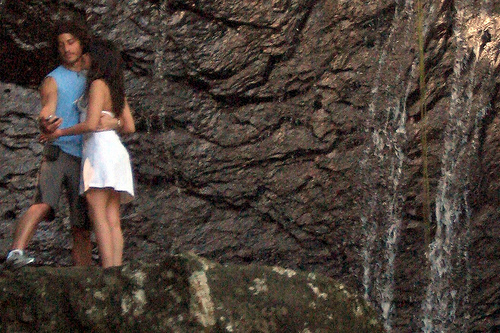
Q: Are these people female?
A: No, they are both male and female.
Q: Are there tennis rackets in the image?
A: No, there are no tennis rackets.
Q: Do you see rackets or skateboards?
A: No, there are no rackets or skateboards.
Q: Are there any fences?
A: No, there are no fences.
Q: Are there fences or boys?
A: No, there are no fences or boys.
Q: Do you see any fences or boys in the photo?
A: No, there are no fences or boys.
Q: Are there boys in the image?
A: No, there are no boys.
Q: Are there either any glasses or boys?
A: No, there are no boys or glasses.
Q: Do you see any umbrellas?
A: No, there are no umbrellas.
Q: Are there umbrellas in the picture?
A: No, there are no umbrellas.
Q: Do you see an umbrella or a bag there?
A: No, there are no umbrellas or bags.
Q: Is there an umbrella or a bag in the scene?
A: No, there are no umbrellas or bags.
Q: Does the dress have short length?
A: Yes, the dress is short.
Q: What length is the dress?
A: The dress is short.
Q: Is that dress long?
A: No, the dress is short.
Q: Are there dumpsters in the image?
A: No, there are no dumpsters.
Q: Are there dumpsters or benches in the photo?
A: No, there are no dumpsters or benches.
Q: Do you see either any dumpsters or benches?
A: No, there are no dumpsters or benches.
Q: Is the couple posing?
A: Yes, the couple is posing.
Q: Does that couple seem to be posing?
A: Yes, the couple is posing.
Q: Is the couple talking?
A: No, the couple is posing.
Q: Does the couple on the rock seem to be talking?
A: No, the couple is posing.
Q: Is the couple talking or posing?
A: The couple is posing.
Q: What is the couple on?
A: The couple is on the rock.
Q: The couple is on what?
A: The couple is on the rock.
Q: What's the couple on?
A: The couple is on the rock.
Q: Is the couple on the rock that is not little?
A: Yes, the couple is on the rock.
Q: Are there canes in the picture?
A: No, there are no canes.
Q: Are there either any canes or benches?
A: No, there are no canes or benches.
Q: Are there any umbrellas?
A: No, there are no umbrellas.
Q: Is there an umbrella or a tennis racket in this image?
A: No, there are no umbrellas or rackets.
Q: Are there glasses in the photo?
A: No, there are no glasses.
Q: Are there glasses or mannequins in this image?
A: No, there are no glasses or mannequins.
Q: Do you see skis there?
A: No, there are no skis.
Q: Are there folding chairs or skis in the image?
A: No, there are no skis or folding chairs.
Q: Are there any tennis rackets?
A: No, there are no tennis rackets.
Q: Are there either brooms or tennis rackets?
A: No, there are no tennis rackets or brooms.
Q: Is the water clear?
A: Yes, the water is clear.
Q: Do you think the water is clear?
A: Yes, the water is clear.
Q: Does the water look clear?
A: Yes, the water is clear.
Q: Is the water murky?
A: No, the water is clear.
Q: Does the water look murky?
A: No, the water is clear.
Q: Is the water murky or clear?
A: The water is clear.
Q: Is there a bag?
A: No, there are no bags.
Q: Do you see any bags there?
A: No, there are no bags.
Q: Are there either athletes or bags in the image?
A: No, there are no bags or athletes.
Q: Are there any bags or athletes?
A: No, there are no bags or athletes.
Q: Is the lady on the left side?
A: Yes, the lady is on the left of the image.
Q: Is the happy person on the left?
A: Yes, the lady is on the left of the image.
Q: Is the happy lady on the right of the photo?
A: No, the lady is on the left of the image.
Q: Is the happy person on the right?
A: No, the lady is on the left of the image.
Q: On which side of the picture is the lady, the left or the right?
A: The lady is on the left of the image.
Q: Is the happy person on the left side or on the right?
A: The lady is on the left of the image.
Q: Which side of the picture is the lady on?
A: The lady is on the left of the image.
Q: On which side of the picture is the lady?
A: The lady is on the left of the image.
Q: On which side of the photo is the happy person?
A: The lady is on the left of the image.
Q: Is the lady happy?
A: Yes, the lady is happy.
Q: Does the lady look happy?
A: Yes, the lady is happy.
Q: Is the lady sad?
A: No, the lady is happy.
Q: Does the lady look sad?
A: No, the lady is happy.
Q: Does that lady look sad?
A: No, the lady is happy.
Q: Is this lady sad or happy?
A: The lady is happy.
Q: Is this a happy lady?
A: Yes, this is a happy lady.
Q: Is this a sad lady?
A: No, this is a happy lady.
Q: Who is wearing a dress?
A: The lady is wearing a dress.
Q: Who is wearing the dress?
A: The lady is wearing a dress.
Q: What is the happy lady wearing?
A: The lady is wearing a dress.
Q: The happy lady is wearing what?
A: The lady is wearing a dress.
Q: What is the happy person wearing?
A: The lady is wearing a dress.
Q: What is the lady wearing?
A: The lady is wearing a dress.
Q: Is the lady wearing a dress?
A: Yes, the lady is wearing a dress.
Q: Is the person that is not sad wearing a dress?
A: Yes, the lady is wearing a dress.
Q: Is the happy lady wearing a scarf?
A: No, the lady is wearing a dress.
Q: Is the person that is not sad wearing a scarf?
A: No, the lady is wearing a dress.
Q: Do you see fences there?
A: No, there are no fences.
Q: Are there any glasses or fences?
A: No, there are no fences or glasses.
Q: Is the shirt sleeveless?
A: Yes, the shirt is sleeveless.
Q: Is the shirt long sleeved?
A: No, the shirt is sleeveless.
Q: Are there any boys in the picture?
A: No, there are no boys.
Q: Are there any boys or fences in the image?
A: No, there are no boys or fences.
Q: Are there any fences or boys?
A: No, there are no boys or fences.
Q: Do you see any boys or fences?
A: No, there are no boys or fences.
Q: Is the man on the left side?
A: Yes, the man is on the left of the image.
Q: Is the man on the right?
A: No, the man is on the left of the image.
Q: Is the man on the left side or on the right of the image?
A: The man is on the left of the image.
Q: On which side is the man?
A: The man is on the left of the image.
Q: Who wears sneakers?
A: The man wears sneakers.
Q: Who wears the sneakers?
A: The man wears sneakers.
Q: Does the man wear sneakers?
A: Yes, the man wears sneakers.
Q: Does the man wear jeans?
A: No, the man wears sneakers.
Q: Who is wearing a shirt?
A: The man is wearing a shirt.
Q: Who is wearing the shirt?
A: The man is wearing a shirt.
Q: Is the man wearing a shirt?
A: Yes, the man is wearing a shirt.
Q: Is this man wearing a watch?
A: No, the man is wearing a shirt.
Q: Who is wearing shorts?
A: The man is wearing shorts.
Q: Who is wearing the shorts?
A: The man is wearing shorts.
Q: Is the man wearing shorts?
A: Yes, the man is wearing shorts.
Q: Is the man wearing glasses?
A: No, the man is wearing shorts.